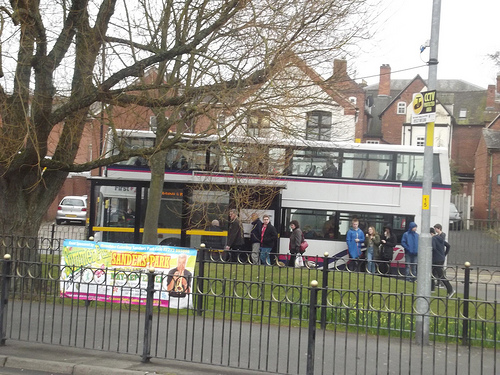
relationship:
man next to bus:
[225, 209, 246, 262] [93, 127, 451, 274]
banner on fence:
[58, 239, 199, 310] [258, 263, 475, 370]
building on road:
[46, 51, 500, 251] [40, 214, 486, 347]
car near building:
[56, 195, 88, 225] [46, 51, 500, 251]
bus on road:
[93, 127, 451, 274] [0, 189, 498, 304]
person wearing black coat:
[288, 220, 308, 267] [258, 218, 279, 248]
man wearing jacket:
[219, 200, 249, 257] [225, 222, 240, 242]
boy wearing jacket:
[330, 182, 412, 303] [348, 231, 368, 250]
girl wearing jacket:
[367, 226, 379, 274] [367, 233, 379, 248]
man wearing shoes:
[426, 226, 458, 300] [421, 274, 459, 300]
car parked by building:
[56, 193, 88, 223] [12, 42, 493, 251]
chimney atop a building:
[375, 61, 393, 97] [12, 42, 493, 251]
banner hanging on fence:
[59, 236, 199, 312] [7, 219, 497, 372]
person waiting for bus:
[288, 220, 304, 265] [93, 127, 451, 274]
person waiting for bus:
[345, 217, 364, 269] [93, 127, 451, 274]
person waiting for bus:
[400, 221, 417, 281] [93, 127, 451, 274]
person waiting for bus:
[258, 213, 278, 265] [93, 127, 451, 274]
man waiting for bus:
[225, 209, 246, 262] [93, 127, 451, 274]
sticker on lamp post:
[421, 192, 429, 211] [414, 0, 444, 346]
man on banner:
[166, 256, 196, 303] [59, 236, 199, 312]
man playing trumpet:
[166, 256, 196, 303] [173, 266, 185, 294]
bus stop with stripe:
[89, 175, 283, 267] [88, 224, 231, 242]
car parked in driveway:
[56, 195, 88, 225] [21, 198, 91, 256]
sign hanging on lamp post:
[406, 85, 440, 126] [407, 0, 445, 345]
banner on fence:
[58, 239, 199, 310] [5, 248, 495, 372]